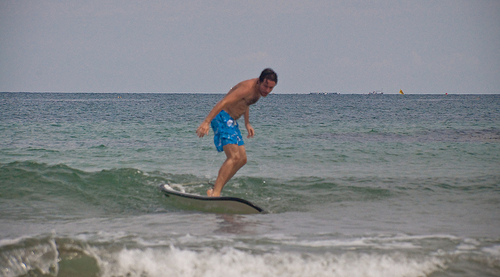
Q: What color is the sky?
A: Blue.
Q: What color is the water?
A: Blue.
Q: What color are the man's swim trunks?
A: Blue.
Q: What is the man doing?
A: Surfboarding.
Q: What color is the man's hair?
A: Brown.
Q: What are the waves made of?
A: Water.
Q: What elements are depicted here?
A: Water and air.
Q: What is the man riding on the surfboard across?
A: Waves.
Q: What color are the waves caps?
A: White.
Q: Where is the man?
A: In ocean.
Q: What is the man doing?
A: Surfing.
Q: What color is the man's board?
A: White.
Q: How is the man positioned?
A: Leaned over.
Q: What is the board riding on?
A: Wave.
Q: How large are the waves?
A: Small.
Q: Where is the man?
A: In the ocean.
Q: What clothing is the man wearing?
A: Shorts.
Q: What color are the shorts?
A: Blue.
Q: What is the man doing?
A: Surfing.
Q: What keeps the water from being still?
A: Waves.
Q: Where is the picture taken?
A: The beach.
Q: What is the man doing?
A: Surfing.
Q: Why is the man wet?
A: He is in the water.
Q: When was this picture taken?
A: Cloudy day.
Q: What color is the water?
A: Green.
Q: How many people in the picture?
A: One man.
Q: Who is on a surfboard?
A: A guy.